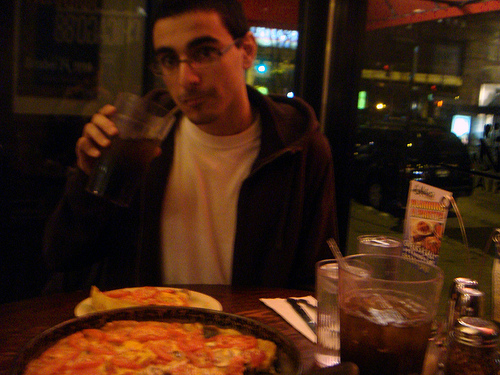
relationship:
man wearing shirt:
[40, 3, 338, 300] [162, 114, 259, 284]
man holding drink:
[25, 3, 337, 294] [88, 86, 175, 211]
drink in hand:
[88, 86, 175, 211] [56, 97, 118, 179]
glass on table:
[310, 256, 366, 372] [247, 305, 289, 331]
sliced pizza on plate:
[79, 281, 204, 308] [72, 285, 223, 320]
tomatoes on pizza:
[186, 343, 196, 355] [6, 304, 315, 364]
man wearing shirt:
[40, 3, 338, 300] [171, 107, 236, 292]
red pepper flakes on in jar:
[445, 342, 498, 372] [441, 314, 498, 373]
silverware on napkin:
[285, 293, 318, 333] [257, 290, 320, 344]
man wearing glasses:
[40, 3, 338, 300] [151, 38, 240, 75]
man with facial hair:
[40, 3, 338, 300] [176, 86, 226, 122]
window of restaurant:
[249, 26, 300, 50] [3, 3, 498, 374]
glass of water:
[310, 256, 366, 372] [315, 263, 371, 368]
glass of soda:
[325, 234, 445, 372] [337, 285, 434, 372]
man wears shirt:
[40, 3, 338, 300] [88, 98, 304, 250]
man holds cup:
[40, 3, 338, 300] [87, 88, 182, 213]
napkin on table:
[260, 294, 317, 344] [0, 287, 318, 374]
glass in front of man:
[310, 256, 350, 366] [124, 180, 341, 369]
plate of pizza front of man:
[70, 283, 224, 315] [40, 3, 338, 300]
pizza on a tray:
[35, 323, 275, 373] [17, 304, 301, 373]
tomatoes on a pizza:
[186, 343, 196, 355] [34, 314, 287, 371]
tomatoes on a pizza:
[94, 314, 190, 359] [37, 307, 289, 372]